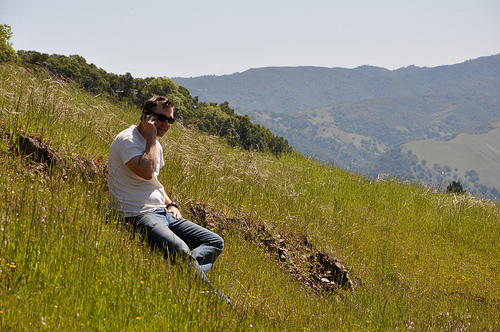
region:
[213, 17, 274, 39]
Part of the sky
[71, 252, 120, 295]
Part of the grass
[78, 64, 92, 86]
Part of the trees in distance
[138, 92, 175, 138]
The head of the person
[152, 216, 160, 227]
Part of the pants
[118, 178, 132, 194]
Part of the white shirt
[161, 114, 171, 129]
The nose of the person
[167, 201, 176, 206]
Part of the watch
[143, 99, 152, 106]
Part of the hair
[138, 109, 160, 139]
The right hand of the person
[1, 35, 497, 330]
The hillside is covered with grass.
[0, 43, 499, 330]
The grass is green.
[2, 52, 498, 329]
The grass is slightly overgrown.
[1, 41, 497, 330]
A man is sitting on the grass.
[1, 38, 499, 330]
The man is wearing sunglasses.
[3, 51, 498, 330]
The man is holding a cell phone to his ear.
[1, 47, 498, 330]
The man is overlooking the hillside.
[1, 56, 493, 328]
The man is wearing a watch on his left wrist.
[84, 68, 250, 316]
The man is wearing blue jeans.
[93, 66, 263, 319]
The man is wearing a white shirt.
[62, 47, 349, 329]
a man sitting outside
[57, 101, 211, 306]
a man sitting in the grass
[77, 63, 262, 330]
a man sitting in a field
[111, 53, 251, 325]
a man wearing glasses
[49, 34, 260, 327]
a man wearing sunglasses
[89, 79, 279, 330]
a man wearing a shirt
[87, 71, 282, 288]
a man wearin ga white shirt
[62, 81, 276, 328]
a man wearing pants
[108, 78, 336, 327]
a man talking on the phone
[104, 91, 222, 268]
a man tlaking on a cell phone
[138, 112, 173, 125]
Sunglasses on man's face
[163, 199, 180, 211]
Watch on man's wrist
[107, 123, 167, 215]
White t shirt on man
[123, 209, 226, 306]
Blue denim jeans on man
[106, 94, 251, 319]
Man sitting on the side of a hil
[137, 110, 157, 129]
Cell phone in man's hand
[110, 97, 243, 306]
Man talking on cell phone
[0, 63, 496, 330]
Grass covered ground on hill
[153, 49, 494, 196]
Mountains in background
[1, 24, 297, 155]
Trees in background of hill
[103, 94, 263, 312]
a man sitting in the grass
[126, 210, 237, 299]
a pair of blue jeans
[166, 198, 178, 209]
a black wrist watch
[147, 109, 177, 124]
a pair of dark sunglasses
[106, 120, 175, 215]
a white shirt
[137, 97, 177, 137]
a man talking on the phone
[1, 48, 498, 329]
a grass covered hill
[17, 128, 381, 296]
clumps of dirt on the hill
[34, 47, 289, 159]
bushes and trees on the hill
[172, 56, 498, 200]
mountains behind the hill